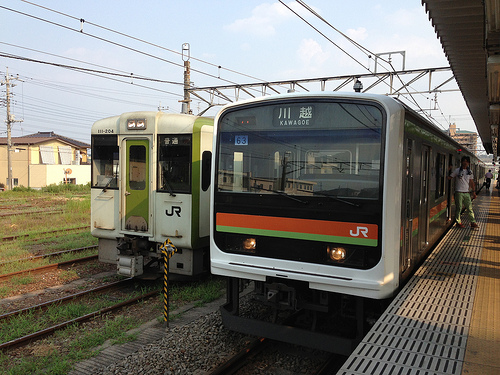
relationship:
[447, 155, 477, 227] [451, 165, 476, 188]
man has t-shirt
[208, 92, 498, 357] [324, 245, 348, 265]
train has headlight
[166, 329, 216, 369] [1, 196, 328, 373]
gravel on ground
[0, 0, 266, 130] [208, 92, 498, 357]
line above train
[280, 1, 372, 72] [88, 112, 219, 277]
line above train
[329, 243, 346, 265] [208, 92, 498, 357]
headlight on train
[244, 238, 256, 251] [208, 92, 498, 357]
head light on train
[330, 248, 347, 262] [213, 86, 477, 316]
headlight of train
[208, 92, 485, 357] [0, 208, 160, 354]
train on tracks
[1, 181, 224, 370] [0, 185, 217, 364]
grass on tracks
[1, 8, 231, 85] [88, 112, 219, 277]
line above train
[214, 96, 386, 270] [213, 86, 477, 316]
window above train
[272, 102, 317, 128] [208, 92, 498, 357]
sign on train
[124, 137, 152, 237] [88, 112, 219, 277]
door on train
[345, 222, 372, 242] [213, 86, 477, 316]
logo on train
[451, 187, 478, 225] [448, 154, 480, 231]
pants on man